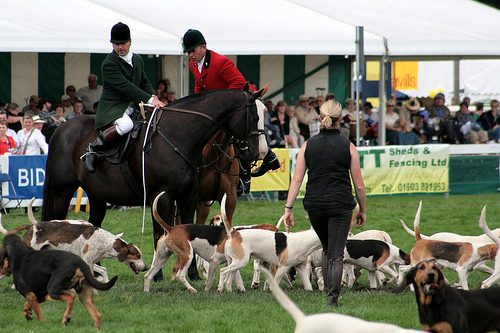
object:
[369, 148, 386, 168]
letter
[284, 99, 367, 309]
woman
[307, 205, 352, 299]
pants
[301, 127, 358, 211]
shirt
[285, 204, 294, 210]
bracelet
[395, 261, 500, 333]
dog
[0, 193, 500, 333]
ground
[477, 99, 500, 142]
spectator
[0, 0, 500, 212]
stand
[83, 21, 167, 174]
man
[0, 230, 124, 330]
dog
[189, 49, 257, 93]
coat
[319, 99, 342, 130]
hair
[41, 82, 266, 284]
horse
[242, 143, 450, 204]
advertisement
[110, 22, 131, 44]
hat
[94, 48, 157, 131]
coat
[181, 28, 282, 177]
rider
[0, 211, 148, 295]
beagle